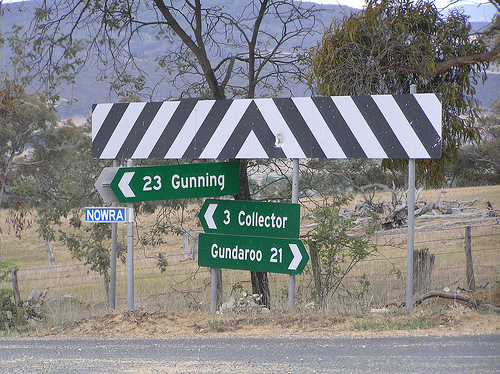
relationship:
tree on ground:
[283, 25, 462, 175] [6, 169, 492, 325]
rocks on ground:
[215, 289, 276, 319] [6, 181, 498, 338]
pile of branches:
[325, 178, 490, 250] [339, 170, 488, 228]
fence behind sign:
[314, 232, 409, 303] [97, 160, 238, 194]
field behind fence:
[1, 182, 497, 333] [0, 222, 498, 313]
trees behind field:
[299, 3, 492, 187] [1, 182, 497, 333]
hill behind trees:
[3, 187, 490, 299] [299, 3, 492, 187]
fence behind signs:
[0, 222, 498, 313] [82, 92, 442, 319]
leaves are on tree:
[333, 26, 360, 47] [290, 1, 494, 188]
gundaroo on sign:
[206, 225, 322, 274] [204, 234, 304, 274]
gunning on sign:
[170, 172, 231, 191] [115, 163, 243, 202]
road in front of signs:
[1, 339, 499, 373] [194, 196, 312, 277]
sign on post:
[195, 230, 310, 275] [283, 272, 299, 303]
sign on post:
[195, 230, 310, 275] [207, 265, 221, 316]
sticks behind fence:
[355, 180, 478, 226] [350, 222, 491, 284]